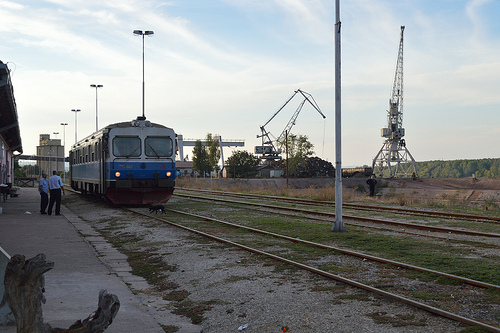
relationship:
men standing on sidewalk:
[47, 169, 65, 216] [6, 187, 64, 247]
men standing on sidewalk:
[38, 172, 50, 215] [6, 180, 72, 252]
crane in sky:
[368, 21, 418, 181] [353, 5, 484, 108]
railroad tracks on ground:
[122, 204, 500, 333] [116, 194, 381, 330]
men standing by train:
[33, 165, 68, 216] [66, 116, 177, 209]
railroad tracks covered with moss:
[122, 204, 500, 333] [285, 220, 375, 255]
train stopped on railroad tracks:
[66, 116, 177, 209] [122, 204, 500, 333]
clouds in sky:
[132, 58, 315, 100] [3, 2, 333, 107]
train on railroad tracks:
[66, 112, 183, 215] [122, 204, 500, 333]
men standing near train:
[39, 169, 63, 219] [66, 116, 177, 209]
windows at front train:
[109, 132, 172, 160] [66, 116, 177, 209]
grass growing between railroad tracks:
[173, 189, 499, 282] [122, 204, 500, 333]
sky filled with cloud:
[5, 2, 496, 167] [0, 1, 498, 97]